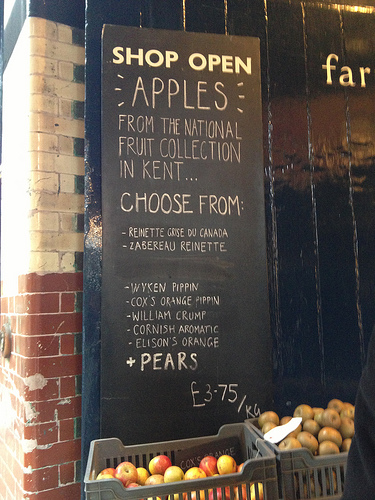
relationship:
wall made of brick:
[0, 0, 90, 499] [12, 291, 59, 316]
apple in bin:
[146, 454, 172, 478] [82, 421, 284, 499]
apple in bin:
[114, 459, 139, 486] [82, 421, 284, 499]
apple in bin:
[160, 465, 185, 488] [82, 421, 284, 499]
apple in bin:
[182, 466, 209, 487] [82, 421, 284, 499]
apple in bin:
[142, 473, 166, 492] [82, 421, 284, 499]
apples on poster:
[111, 71, 249, 120] [97, 22, 279, 454]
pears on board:
[138, 351, 200, 375] [97, 22, 279, 454]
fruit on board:
[116, 133, 157, 160] [97, 22, 279, 454]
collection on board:
[158, 135, 246, 165] [97, 22, 279, 454]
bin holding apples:
[82, 421, 284, 499] [95, 453, 264, 500]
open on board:
[186, 51, 255, 77] [97, 22, 279, 454]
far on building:
[320, 49, 374, 94] [1, 1, 374, 500]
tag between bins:
[259, 414, 305, 446] [81, 396, 368, 499]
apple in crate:
[114, 459, 139, 486] [82, 421, 284, 499]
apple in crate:
[215, 451, 238, 476] [82, 421, 284, 499]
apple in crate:
[198, 454, 221, 476] [82, 421, 284, 499]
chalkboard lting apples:
[97, 22, 279, 454] [119, 227, 232, 255]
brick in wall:
[9, 290, 64, 319] [0, 0, 90, 499]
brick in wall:
[12, 312, 89, 339] [0, 0, 90, 499]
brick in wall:
[9, 331, 65, 361] [0, 0, 90, 499]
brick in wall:
[7, 374, 64, 406] [0, 0, 90, 499]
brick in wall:
[11, 464, 64, 495] [0, 0, 90, 499]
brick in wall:
[15, 16, 62, 45] [0, 0, 90, 499]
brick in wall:
[13, 38, 90, 70] [0, 0, 90, 499]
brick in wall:
[16, 54, 62, 81] [0, 0, 90, 499]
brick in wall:
[13, 92, 64, 120] [0, 0, 90, 499]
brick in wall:
[16, 130, 64, 155] [0, 0, 90, 499]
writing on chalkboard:
[109, 44, 265, 421] [97, 22, 279, 454]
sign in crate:
[259, 414, 305, 446] [244, 397, 373, 498]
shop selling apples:
[1, 1, 374, 500] [95, 453, 264, 500]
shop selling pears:
[1, 1, 374, 500] [138, 351, 200, 375]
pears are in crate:
[253, 397, 374, 461] [244, 397, 373, 498]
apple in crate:
[142, 473, 166, 492] [82, 421, 284, 499]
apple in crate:
[160, 465, 185, 488] [82, 421, 284, 499]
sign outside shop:
[97, 22, 279, 454] [1, 1, 374, 500]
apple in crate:
[146, 454, 172, 478] [82, 421, 284, 499]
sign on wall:
[97, 22, 279, 454] [83, 0, 374, 499]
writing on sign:
[109, 44, 265, 421] [97, 22, 279, 454]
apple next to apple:
[198, 454, 221, 476] [215, 451, 238, 476]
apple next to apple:
[182, 466, 209, 487] [198, 454, 221, 476]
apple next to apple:
[160, 465, 185, 488] [182, 466, 209, 487]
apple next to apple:
[146, 454, 172, 478] [142, 473, 166, 492]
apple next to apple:
[114, 459, 139, 486] [134, 462, 150, 486]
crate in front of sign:
[244, 397, 373, 498] [97, 22, 279, 454]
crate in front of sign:
[82, 421, 284, 499] [97, 22, 279, 454]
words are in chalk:
[109, 44, 265, 421] [110, 72, 265, 422]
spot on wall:
[83, 213, 115, 262] [83, 0, 374, 499]